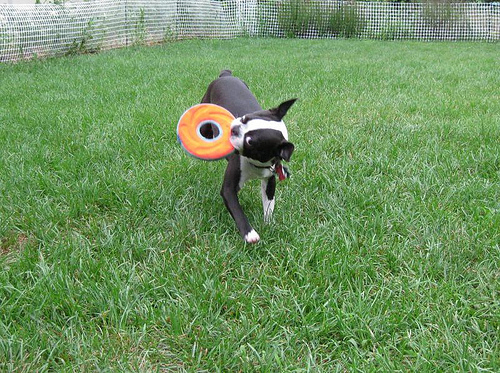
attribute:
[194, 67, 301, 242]
boston terrier — white, black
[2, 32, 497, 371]
grass — bright, green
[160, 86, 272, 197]
frisbee — orange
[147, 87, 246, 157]
frisbee — round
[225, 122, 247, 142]
nose — black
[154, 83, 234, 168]
ring — flying